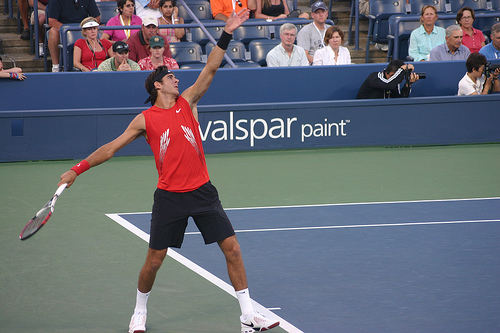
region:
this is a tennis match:
[56, 25, 319, 246]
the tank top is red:
[85, 90, 223, 237]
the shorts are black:
[142, 177, 243, 255]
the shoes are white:
[127, 268, 286, 328]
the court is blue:
[310, 258, 442, 321]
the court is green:
[293, 164, 382, 195]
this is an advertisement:
[222, 102, 379, 163]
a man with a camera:
[386, 58, 426, 89]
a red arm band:
[68, 139, 108, 186]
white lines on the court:
[268, 194, 334, 252]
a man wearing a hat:
[138, 69, 195, 111]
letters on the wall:
[198, 107, 359, 148]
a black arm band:
[206, 19, 246, 64]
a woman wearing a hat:
[138, 23, 176, 67]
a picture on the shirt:
[144, 116, 204, 166]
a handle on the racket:
[38, 173, 82, 212]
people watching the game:
[258, 11, 368, 68]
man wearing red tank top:
[141, 88, 215, 190]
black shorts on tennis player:
[143, 175, 238, 254]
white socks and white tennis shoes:
[128, 275, 283, 330]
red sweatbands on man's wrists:
[67, 154, 93, 178]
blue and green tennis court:
[11, 148, 499, 320]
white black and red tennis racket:
[17, 180, 72, 244]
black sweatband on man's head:
[147, 66, 177, 94]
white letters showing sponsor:
[196, 108, 353, 145]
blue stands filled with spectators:
[5, 10, 491, 160]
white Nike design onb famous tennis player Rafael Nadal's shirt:
[157, 121, 209, 173]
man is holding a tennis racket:
[18, 175, 67, 243]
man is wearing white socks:
[133, 287, 253, 317]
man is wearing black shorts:
[146, 185, 239, 245]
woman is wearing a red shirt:
[74, 39, 111, 71]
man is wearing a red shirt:
[139, 97, 211, 187]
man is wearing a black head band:
[138, 69, 175, 88]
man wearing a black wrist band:
[214, 30, 232, 49]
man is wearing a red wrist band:
[71, 160, 91, 174]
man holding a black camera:
[403, 66, 425, 86]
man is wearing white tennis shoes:
[127, 313, 281, 330]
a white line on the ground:
[286, 186, 378, 246]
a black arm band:
[196, 29, 260, 56]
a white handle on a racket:
[37, 158, 87, 218]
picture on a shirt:
[146, 105, 233, 177]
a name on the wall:
[191, 104, 367, 152]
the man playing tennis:
[17, 7, 281, 329]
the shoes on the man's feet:
[128, 304, 279, 331]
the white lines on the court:
[104, 194, 498, 331]